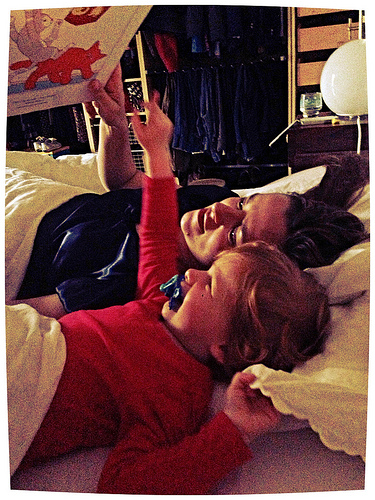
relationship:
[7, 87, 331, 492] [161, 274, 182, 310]
child has pacifier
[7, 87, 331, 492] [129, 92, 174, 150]
child has hand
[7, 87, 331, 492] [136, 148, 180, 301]
child has arm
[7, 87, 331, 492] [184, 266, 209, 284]
child has nose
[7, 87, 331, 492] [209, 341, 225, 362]
child has ear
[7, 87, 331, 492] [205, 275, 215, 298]
child has eye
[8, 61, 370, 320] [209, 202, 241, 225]
woman has nose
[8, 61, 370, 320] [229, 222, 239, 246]
woman has eye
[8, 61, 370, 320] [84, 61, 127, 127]
woman has hand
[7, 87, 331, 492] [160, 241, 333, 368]
child has head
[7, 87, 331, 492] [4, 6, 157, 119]
child reading book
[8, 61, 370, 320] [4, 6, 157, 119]
woman reading book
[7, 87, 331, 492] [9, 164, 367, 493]
child in bed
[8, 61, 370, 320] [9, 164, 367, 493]
woman in bed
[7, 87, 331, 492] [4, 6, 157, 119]
child pointing at book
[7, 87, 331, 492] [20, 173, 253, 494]
child wearing shirt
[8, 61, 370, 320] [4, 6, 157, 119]
woman holding book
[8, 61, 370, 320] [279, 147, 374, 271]
woman has hair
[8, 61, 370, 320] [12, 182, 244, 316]
woman wearing top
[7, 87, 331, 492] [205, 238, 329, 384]
child has hair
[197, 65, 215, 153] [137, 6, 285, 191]
jeans in closet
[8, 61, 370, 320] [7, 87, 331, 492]
woman reading to child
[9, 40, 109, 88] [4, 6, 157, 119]
character in book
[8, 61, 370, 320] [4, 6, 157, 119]
woman has book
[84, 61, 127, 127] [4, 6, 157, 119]
hand holding book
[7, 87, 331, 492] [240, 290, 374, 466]
child holding pillow case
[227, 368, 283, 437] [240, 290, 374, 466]
hand holding pillow case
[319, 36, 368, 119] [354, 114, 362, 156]
lamp shade on base